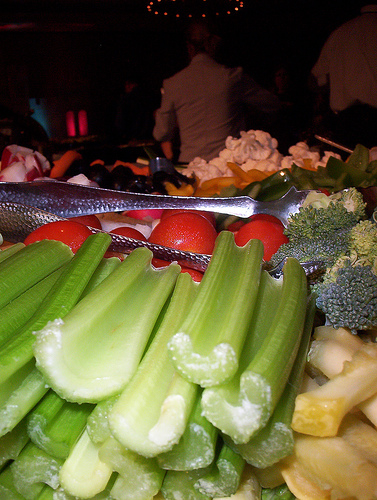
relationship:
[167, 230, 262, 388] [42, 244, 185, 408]
celery stacked on celery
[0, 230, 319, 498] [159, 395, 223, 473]
celery stacked on celery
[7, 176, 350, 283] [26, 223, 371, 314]
tongs on vegetables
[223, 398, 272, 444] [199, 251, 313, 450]
stuff on celery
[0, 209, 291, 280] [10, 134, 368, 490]
tomato on platter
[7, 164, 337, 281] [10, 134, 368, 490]
utensil for grabbing on platter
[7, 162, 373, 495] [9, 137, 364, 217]
vegetables and fruits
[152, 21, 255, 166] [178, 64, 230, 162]
woman turning her back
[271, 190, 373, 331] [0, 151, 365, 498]
broccoli on table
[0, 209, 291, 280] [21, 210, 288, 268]
tomato in a pile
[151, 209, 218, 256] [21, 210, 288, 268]
tomato in a pile